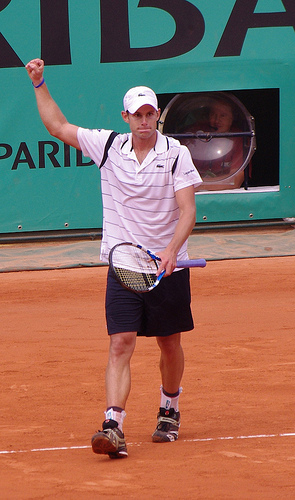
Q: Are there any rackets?
A: Yes, there is a racket.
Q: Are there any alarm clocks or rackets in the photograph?
A: Yes, there is a racket.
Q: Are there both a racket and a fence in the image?
A: No, there is a racket but no fences.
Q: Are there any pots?
A: No, there are no pots.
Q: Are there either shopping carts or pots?
A: No, there are no pots or shopping carts.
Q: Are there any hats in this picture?
A: Yes, there is a hat.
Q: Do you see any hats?
A: Yes, there is a hat.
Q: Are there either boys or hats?
A: Yes, there is a hat.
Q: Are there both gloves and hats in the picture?
A: No, there is a hat but no gloves.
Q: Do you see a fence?
A: No, there are no fences.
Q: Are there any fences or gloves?
A: No, there are no fences or gloves.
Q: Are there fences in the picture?
A: No, there are no fences.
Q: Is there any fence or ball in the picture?
A: No, there are no fences or balls.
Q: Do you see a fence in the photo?
A: No, there are no fences.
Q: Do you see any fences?
A: No, there are no fences.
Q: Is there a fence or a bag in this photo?
A: No, there are no fences or bags.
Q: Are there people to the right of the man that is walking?
A: Yes, there is a person to the right of the man.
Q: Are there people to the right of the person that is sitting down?
A: Yes, there is a person to the right of the man.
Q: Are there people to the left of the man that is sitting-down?
A: No, the person is to the right of the man.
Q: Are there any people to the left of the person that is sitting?
A: No, the person is to the right of the man.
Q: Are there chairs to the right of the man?
A: No, there is a person to the right of the man.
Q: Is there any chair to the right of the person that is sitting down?
A: No, there is a person to the right of the man.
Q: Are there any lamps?
A: No, there are no lamps.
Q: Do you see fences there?
A: No, there are no fences.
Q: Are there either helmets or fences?
A: No, there are no fences or helmets.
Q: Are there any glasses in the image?
A: No, there are no glasses.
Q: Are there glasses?
A: No, there are no glasses.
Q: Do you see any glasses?
A: No, there are no glasses.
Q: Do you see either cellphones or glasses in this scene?
A: No, there are no glasses or cellphones.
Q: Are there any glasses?
A: No, there are no glasses.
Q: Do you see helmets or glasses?
A: No, there are no glasses or helmets.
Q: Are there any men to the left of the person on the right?
A: Yes, there is a man to the left of the person.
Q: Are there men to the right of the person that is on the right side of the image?
A: No, the man is to the left of the person.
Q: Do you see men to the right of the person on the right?
A: No, the man is to the left of the person.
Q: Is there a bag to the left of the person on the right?
A: No, there is a man to the left of the person.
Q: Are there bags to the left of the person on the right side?
A: No, there is a man to the left of the person.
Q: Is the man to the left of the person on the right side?
A: Yes, the man is to the left of the person.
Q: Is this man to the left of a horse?
A: No, the man is to the left of the person.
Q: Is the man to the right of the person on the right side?
A: No, the man is to the left of the person.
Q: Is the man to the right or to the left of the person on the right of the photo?
A: The man is to the left of the person.